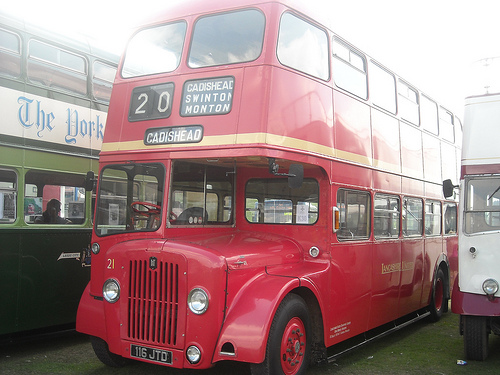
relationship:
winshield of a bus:
[96, 157, 323, 231] [71, 8, 458, 355]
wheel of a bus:
[126, 197, 179, 220] [71, 8, 458, 355]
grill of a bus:
[120, 248, 186, 348] [71, 8, 458, 355]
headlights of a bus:
[99, 273, 210, 314] [71, 8, 458, 355]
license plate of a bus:
[128, 342, 173, 363] [71, 8, 458, 355]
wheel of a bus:
[265, 288, 328, 372] [71, 8, 458, 355]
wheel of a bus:
[428, 262, 448, 319] [71, 8, 458, 355]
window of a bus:
[442, 201, 458, 236] [71, 8, 458, 355]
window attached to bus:
[234, 171, 340, 231] [71, 8, 458, 355]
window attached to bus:
[442, 201, 458, 236] [71, 8, 458, 355]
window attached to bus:
[431, 190, 460, 250] [71, 8, 458, 355]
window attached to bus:
[187, 8, 266, 69] [95, 5, 472, 368]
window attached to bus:
[357, 52, 403, 117] [95, 5, 472, 368]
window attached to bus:
[367, 59, 398, 116] [95, 5, 472, 368]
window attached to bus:
[166, 150, 237, 225] [95, 5, 472, 368]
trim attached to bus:
[99, 142, 463, 188] [95, 5, 472, 368]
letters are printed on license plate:
[120, 340, 180, 364] [130, 343, 174, 366]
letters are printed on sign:
[140, 126, 207, 142] [141, 120, 210, 150]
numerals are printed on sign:
[120, 76, 177, 119] [120, 73, 190, 116]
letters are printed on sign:
[182, 77, 231, 109] [178, 73, 238, 112]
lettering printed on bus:
[377, 250, 437, 285] [81, 11, 441, 372]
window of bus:
[96, 163, 162, 235] [71, 8, 458, 355]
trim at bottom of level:
[97, 139, 457, 188] [99, 0, 459, 179]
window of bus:
[442, 201, 458, 236] [71, 8, 458, 355]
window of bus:
[187, 8, 266, 69] [71, 8, 458, 355]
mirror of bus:
[441, 178, 453, 197] [442, 92, 499, 357]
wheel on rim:
[250, 290, 312, 374] [279, 316, 304, 372]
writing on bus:
[379, 255, 420, 273] [71, 8, 458, 355]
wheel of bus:
[250, 290, 312, 374] [71, 8, 458, 355]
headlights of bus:
[99, 273, 210, 314] [71, 8, 458, 355]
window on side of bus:
[442, 201, 458, 236] [71, 8, 458, 355]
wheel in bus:
[129, 200, 179, 222] [71, 8, 458, 355]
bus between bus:
[71, 8, 458, 355] [0, 12, 130, 343]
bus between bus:
[71, 8, 458, 355] [442, 92, 499, 357]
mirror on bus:
[441, 179, 454, 198] [447, 88, 498, 357]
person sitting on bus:
[41, 197, 70, 222] [3, 12, 254, 340]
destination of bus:
[179, 77, 233, 112] [71, 8, 458, 355]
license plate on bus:
[130, 343, 174, 366] [71, 8, 458, 355]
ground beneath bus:
[2, 309, 499, 373] [442, 92, 499, 357]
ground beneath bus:
[2, 309, 499, 373] [71, 8, 458, 355]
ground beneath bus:
[2, 309, 499, 373] [0, 12, 227, 345]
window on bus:
[277, 7, 329, 79] [71, 8, 458, 355]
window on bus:
[442, 201, 458, 236] [71, 8, 458, 355]